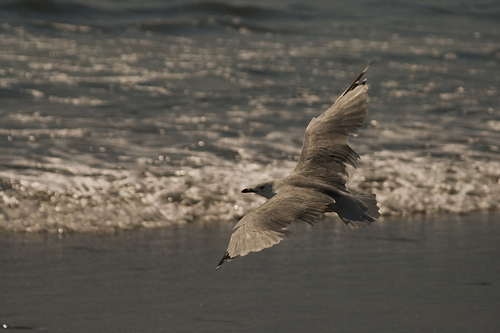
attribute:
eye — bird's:
[258, 186, 266, 191]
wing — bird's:
[302, 68, 371, 180]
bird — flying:
[187, 89, 421, 299]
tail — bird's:
[337, 185, 382, 229]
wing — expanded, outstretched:
[214, 190, 336, 270]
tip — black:
[214, 250, 236, 268]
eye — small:
[255, 186, 263, 193]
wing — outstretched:
[290, 60, 381, 187]